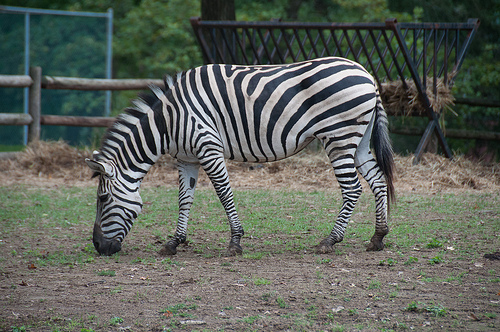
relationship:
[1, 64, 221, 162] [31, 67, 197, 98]
fence made of pole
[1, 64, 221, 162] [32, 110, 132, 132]
fence made of pole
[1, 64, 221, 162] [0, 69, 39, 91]
fence made of pole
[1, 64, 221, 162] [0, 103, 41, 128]
fence made of pole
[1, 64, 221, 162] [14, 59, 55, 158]
fence made of pole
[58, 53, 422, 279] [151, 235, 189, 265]
zebra has hoof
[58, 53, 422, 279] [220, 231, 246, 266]
zebra has hoof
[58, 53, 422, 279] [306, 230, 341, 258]
zebra has hoof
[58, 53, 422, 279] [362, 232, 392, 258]
zebra has hoof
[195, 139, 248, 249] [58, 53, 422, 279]
leg on zebra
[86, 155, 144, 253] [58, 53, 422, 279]
head on zebra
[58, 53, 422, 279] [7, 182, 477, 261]
zebra eating grass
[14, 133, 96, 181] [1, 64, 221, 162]
pile by fence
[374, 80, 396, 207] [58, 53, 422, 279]
tail on zebra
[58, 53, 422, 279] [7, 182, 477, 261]
zebra on grass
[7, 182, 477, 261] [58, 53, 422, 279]
grass being eaten by zebra